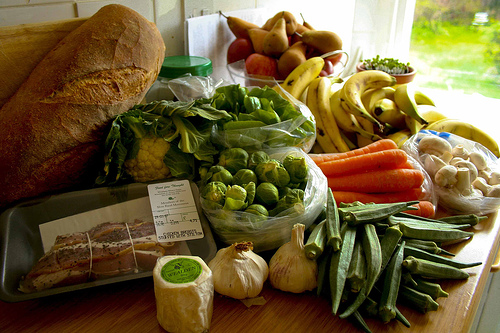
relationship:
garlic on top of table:
[209, 241, 272, 295] [2, 4, 496, 332]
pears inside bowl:
[215, 5, 352, 88] [230, 65, 353, 96]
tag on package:
[146, 181, 202, 239] [7, 179, 223, 299]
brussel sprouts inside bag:
[200, 143, 327, 243] [197, 144, 333, 248]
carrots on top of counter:
[315, 136, 433, 214] [2, 4, 496, 332]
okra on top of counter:
[306, 187, 479, 331] [2, 4, 496, 332]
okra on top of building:
[306, 187, 479, 331] [2, 4, 496, 332]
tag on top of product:
[146, 181, 202, 239] [7, 179, 223, 299]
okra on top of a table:
[306, 187, 479, 331] [2, 4, 496, 332]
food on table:
[2, 4, 496, 332] [19, 103, 480, 312]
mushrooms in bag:
[415, 129, 498, 198] [396, 122, 484, 204]